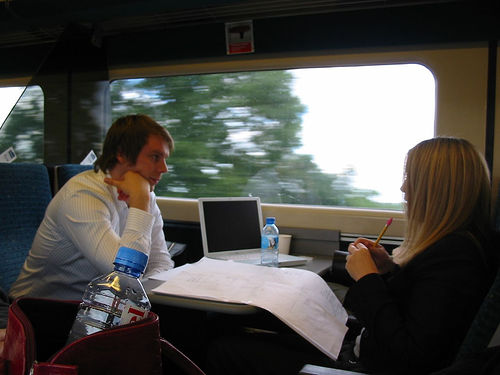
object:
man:
[6, 114, 175, 302]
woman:
[341, 133, 498, 373]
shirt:
[9, 163, 177, 306]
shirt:
[339, 230, 500, 375]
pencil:
[369, 218, 392, 248]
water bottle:
[67, 247, 153, 336]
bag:
[1, 296, 165, 375]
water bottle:
[260, 215, 280, 268]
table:
[142, 224, 334, 316]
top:
[114, 246, 150, 277]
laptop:
[197, 196, 307, 269]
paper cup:
[279, 233, 293, 255]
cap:
[111, 245, 149, 275]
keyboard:
[210, 252, 306, 263]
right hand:
[354, 236, 391, 267]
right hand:
[103, 170, 151, 203]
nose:
[157, 156, 168, 174]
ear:
[116, 144, 125, 164]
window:
[102, 61, 437, 214]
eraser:
[386, 217, 393, 226]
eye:
[149, 154, 161, 162]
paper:
[149, 256, 350, 363]